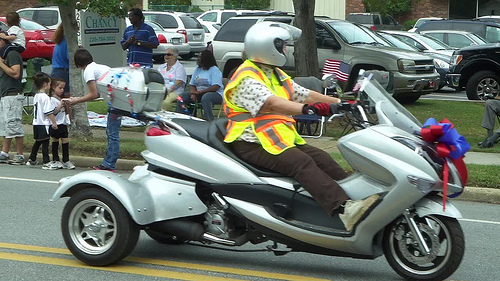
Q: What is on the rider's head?
A: Helmet.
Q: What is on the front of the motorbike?
A: Bow.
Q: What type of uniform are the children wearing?
A: Soccer.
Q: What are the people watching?
A: Parade.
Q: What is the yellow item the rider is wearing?
A: Safety vest.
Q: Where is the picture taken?
A: A parade.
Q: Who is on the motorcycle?
A: A man.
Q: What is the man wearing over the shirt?
A: A safety vest.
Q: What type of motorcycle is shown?
A: Silver.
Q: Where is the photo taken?
A: On the road.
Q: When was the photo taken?
A: In the afternoon.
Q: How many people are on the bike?
A: One.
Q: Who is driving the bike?
A: A woman.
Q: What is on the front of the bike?
A: A bow.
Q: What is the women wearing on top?
A: A vest.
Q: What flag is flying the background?
A: American flag.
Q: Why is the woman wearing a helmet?
A: For safety.